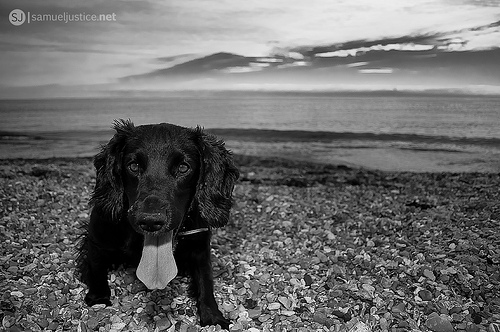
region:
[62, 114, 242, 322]
dog lying on the beach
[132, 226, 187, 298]
tongue of a dog on the beach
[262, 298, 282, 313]
small rock on the beach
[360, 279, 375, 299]
small rock on the beach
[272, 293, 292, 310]
small rock on the beach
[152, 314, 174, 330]
small rock on the beach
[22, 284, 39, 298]
small rock on the beach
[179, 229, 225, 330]
leg of a black dog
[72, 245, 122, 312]
leg of a black dog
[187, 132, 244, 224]
ear of a black dog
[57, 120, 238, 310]
dog on the beach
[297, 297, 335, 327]
rocks on the beach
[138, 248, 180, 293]
tongue of the dog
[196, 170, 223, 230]
ear of the dog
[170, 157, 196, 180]
eye of the dog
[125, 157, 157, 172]
eye of the dog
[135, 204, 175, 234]
nose of the dog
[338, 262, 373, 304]
rocks on the beach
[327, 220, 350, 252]
rocks ont eh beach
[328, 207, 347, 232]
rocks on the beach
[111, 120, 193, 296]
this is a dog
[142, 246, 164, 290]
this is its tongue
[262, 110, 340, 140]
this is the water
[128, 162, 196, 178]
these are the eyes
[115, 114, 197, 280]
the dog is black in colour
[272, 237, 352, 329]
these are stones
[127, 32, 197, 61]
this is the sky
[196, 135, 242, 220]
this is the ear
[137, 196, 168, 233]
this is the nose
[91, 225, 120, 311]
this is the fore limb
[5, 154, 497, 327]
Rocky beach along ocean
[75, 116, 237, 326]
Black dog resting on beach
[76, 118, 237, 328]
Wet dog resting on beach after swim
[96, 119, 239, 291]
Panting dog resting on beach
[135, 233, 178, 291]
Extended tongue of panting dog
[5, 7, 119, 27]
Website of photograph owner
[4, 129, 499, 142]
Small wave breaking on beach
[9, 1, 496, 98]
Clouds in sky over ocean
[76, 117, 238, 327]
Panting dog facing the camera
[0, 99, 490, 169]
Placid ocean off of beach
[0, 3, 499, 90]
white clouds in sky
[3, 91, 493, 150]
surface of calm water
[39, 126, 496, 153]
swelling wave of ocean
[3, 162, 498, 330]
rocks on ocean shore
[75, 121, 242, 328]
dog reclined on rock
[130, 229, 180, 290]
dog tongue hanging out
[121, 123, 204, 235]
face of alert dog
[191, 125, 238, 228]
dog ear with spiked hair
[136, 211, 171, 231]
nose on dog snout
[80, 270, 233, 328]
two paws on rocks